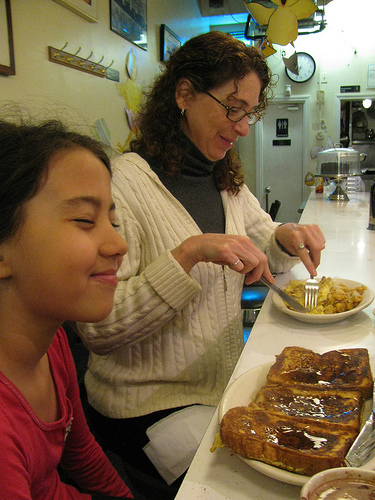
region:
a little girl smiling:
[2, 94, 125, 497]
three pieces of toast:
[214, 340, 373, 476]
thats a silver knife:
[259, 271, 307, 320]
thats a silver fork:
[303, 247, 318, 309]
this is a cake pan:
[312, 143, 362, 201]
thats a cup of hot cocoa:
[302, 465, 373, 497]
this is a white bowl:
[267, 274, 373, 322]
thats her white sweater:
[71, 152, 297, 419]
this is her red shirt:
[3, 326, 135, 497]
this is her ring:
[296, 241, 304, 249]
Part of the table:
[336, 222, 355, 257]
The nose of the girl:
[97, 209, 130, 261]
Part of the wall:
[44, 77, 71, 94]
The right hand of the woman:
[197, 230, 276, 290]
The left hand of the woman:
[272, 220, 333, 277]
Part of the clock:
[304, 62, 310, 75]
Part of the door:
[276, 156, 292, 179]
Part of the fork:
[308, 286, 312, 298]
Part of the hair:
[18, 137, 39, 158]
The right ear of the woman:
[172, 74, 195, 115]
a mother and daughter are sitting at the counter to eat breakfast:
[0, 19, 373, 498]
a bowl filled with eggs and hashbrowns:
[272, 266, 373, 322]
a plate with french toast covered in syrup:
[212, 334, 373, 487]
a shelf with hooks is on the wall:
[44, 40, 116, 80]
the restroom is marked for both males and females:
[257, 94, 306, 224]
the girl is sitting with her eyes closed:
[2, 102, 134, 498]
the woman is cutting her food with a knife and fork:
[76, 25, 331, 499]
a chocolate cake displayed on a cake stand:
[311, 144, 368, 204]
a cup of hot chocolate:
[290, 465, 374, 498]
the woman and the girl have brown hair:
[1, 25, 325, 498]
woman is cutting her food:
[155, 60, 367, 350]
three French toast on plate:
[210, 323, 374, 489]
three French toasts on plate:
[198, 317, 353, 498]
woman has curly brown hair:
[128, 28, 274, 201]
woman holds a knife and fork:
[122, 28, 331, 319]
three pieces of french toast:
[216, 342, 374, 486]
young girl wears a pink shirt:
[4, 116, 137, 498]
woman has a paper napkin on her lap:
[76, 15, 327, 485]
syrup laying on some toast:
[269, 358, 349, 462]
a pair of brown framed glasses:
[166, 83, 262, 126]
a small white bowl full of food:
[266, 271, 374, 324]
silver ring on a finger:
[225, 251, 245, 274]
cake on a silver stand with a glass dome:
[312, 143, 364, 203]